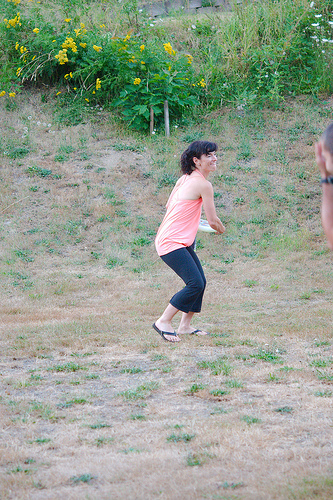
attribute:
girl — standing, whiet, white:
[168, 168, 213, 310]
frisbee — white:
[202, 223, 218, 237]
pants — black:
[168, 246, 207, 291]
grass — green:
[61, 336, 160, 406]